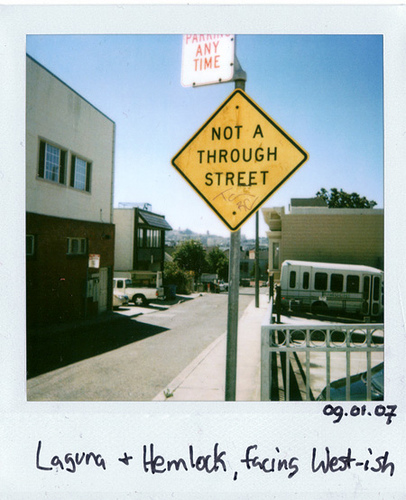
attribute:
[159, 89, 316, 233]
sign — yellow and black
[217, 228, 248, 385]
steel post — galvanized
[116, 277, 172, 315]
cab truck — parked, white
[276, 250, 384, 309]
bus — white, parked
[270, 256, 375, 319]
shuttle bus — small, white and green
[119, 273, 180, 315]
pickup truck — white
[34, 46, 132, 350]
building — two story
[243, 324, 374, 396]
fence — white metal, parking 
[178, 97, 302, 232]
sign — street, red graffiti 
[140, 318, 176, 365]
street — grey pavement 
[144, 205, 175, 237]
overhang — black awning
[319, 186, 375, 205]
trees — green leafy 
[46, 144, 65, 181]
windows — second story  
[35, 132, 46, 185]
shutters — black 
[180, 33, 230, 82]
sign — White square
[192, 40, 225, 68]
letters — red 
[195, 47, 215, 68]
letters — red 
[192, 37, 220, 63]
word — ANY 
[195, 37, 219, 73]
word — TIME 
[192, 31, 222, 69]
letters — red 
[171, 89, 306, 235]
sign — diamond shaped , Yellow,  black writing.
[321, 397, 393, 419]
date — 09.01.07 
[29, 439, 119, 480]
word — Laguna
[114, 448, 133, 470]
symbol — & 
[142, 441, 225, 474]
word — Hemlock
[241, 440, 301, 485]
word — facing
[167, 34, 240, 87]
sign — street , part 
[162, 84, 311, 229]
sign — street , graffiti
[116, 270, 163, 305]
truck — white pickup , part 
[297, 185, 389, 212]
tree — top  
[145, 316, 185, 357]
lot — PARKING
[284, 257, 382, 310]
bus — PASSENGER, SMALL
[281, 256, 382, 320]
bus — WHITE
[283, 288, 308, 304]
stripes — GREEN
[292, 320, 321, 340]
rail — WHITE, METALLIC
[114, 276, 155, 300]
truck — PICK-UP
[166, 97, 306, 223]
sign — CAUTION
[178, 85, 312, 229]
sign — TRIANGLE